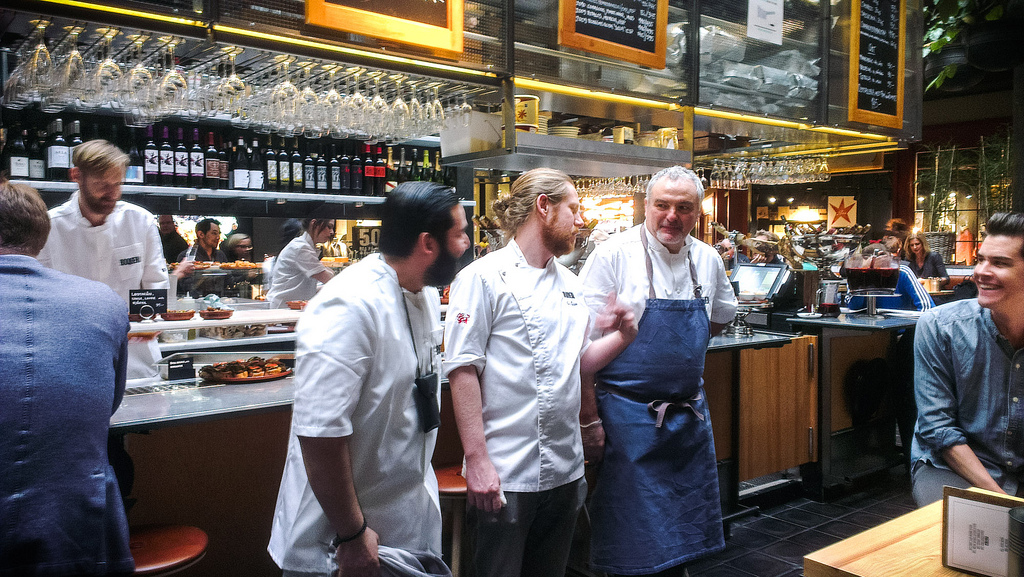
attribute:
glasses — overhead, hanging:
[35, 31, 208, 93]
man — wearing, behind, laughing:
[913, 200, 1019, 357]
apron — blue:
[635, 279, 732, 481]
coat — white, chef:
[436, 239, 695, 516]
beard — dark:
[410, 231, 485, 283]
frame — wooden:
[522, 6, 690, 63]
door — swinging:
[720, 311, 879, 465]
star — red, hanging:
[795, 169, 857, 225]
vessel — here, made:
[164, 255, 258, 323]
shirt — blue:
[918, 312, 1017, 449]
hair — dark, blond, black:
[347, 163, 500, 303]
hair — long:
[482, 149, 638, 236]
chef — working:
[45, 152, 255, 305]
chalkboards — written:
[865, 18, 902, 113]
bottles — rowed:
[139, 112, 403, 193]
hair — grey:
[638, 157, 716, 233]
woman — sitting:
[802, 201, 936, 300]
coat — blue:
[32, 289, 226, 564]